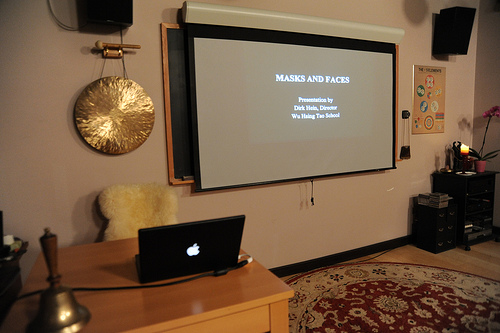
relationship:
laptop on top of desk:
[131, 208, 248, 288] [0, 232, 302, 331]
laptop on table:
[133, 213, 247, 284] [3, 234, 293, 331]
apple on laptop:
[178, 236, 201, 258] [116, 215, 254, 282]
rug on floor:
[272, 261, 492, 329] [404, 239, 498, 272]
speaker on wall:
[431, 4, 477, 55] [1, 0, 490, 272]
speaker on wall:
[69, 2, 144, 36] [1, 0, 490, 272]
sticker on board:
[420, 69, 437, 89] [405, 60, 449, 138]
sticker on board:
[415, 78, 427, 100] [405, 60, 449, 138]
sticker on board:
[416, 96, 428, 114] [405, 60, 449, 138]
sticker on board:
[422, 112, 435, 130] [405, 60, 449, 138]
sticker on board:
[432, 85, 442, 101] [405, 60, 449, 138]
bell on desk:
[18, 229, 95, 330] [1, 214, 316, 331]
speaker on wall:
[431, 6, 477, 55] [0, 0, 480, 240]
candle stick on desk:
[40, 225, 77, 331] [0, 232, 303, 332]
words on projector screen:
[274, 70, 351, 122] [192, 36, 395, 194]